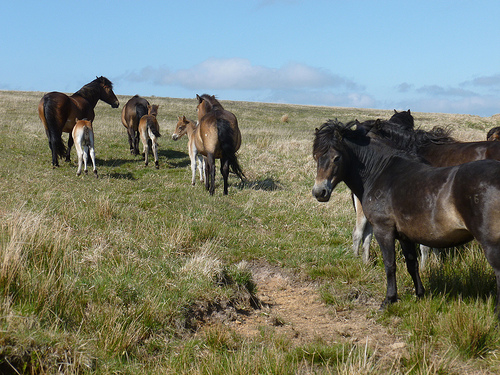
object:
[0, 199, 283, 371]
field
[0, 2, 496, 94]
sky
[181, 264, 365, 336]
brown patch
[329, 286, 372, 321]
dead grass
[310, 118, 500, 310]
animal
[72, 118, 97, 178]
animal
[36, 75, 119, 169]
animal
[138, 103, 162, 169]
animal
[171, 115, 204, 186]
animal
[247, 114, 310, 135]
grass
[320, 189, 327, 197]
nose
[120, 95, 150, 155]
horse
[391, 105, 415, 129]
horse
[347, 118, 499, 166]
horse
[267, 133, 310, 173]
dead grass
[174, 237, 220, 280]
dead grass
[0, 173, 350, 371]
grass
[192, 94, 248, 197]
horse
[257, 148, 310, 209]
grass patch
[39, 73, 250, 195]
animals